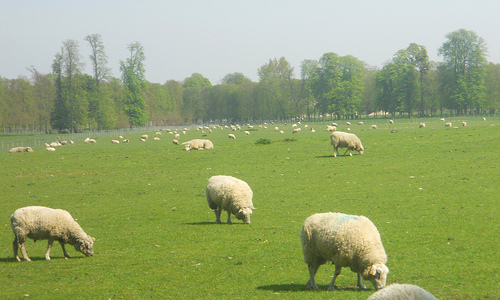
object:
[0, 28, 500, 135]
trees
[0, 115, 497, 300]
field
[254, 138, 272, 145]
bush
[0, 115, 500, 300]
grass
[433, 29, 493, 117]
trees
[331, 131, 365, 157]
sheep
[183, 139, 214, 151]
sheep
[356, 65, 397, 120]
ground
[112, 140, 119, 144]
sheep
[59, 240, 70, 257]
leg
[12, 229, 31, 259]
legs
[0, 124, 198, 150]
fence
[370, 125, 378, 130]
sheep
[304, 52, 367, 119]
trees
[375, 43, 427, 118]
trees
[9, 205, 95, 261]
sheep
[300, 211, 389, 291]
sheep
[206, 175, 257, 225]
sheep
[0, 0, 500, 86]
sky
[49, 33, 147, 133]
tree